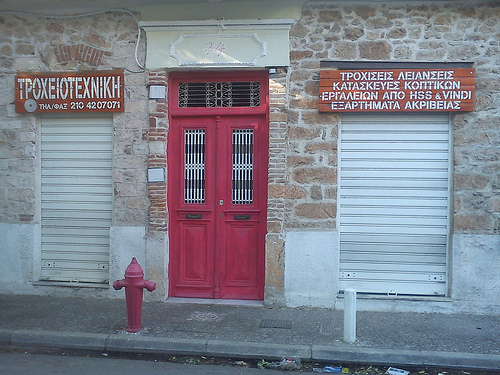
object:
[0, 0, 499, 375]
greece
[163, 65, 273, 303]
door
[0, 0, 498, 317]
building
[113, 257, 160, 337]
fire hydrant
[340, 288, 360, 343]
pole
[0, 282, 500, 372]
sidewalk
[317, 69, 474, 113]
sign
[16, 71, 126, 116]
sign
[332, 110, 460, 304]
window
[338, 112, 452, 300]
metal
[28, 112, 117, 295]
window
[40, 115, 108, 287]
metal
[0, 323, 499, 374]
curb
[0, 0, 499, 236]
stonework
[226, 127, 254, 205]
blind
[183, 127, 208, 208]
blind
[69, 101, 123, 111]
phone number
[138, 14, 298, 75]
lintel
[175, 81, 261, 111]
window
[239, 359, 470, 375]
trash